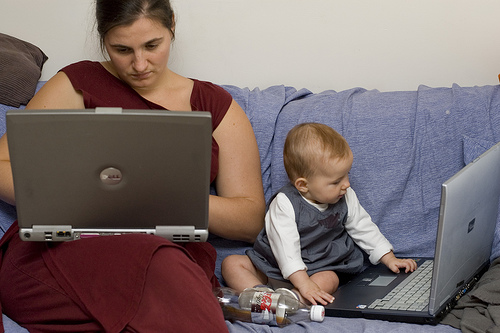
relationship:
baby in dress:
[223, 119, 411, 313] [246, 194, 365, 279]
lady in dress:
[2, 4, 268, 329] [0, 69, 233, 332]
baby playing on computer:
[223, 119, 411, 313] [5, 106, 499, 328]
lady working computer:
[2, 4, 268, 329] [5, 106, 499, 328]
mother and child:
[2, 4, 268, 329] [223, 119, 411, 313]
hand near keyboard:
[382, 244, 418, 276] [327, 257, 436, 316]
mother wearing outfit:
[2, 4, 268, 329] [0, 69, 233, 332]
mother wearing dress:
[2, 4, 268, 329] [246, 194, 365, 279]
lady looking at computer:
[3, 1, 268, 329] [5, 106, 499, 328]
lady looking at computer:
[3, 1, 268, 329] [5, 106, 219, 242]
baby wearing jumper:
[223, 119, 411, 313] [246, 194, 365, 279]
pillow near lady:
[0, 30, 49, 113] [3, 1, 268, 329]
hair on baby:
[280, 123, 350, 174] [223, 119, 411, 313]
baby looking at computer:
[223, 119, 411, 313] [5, 106, 219, 242]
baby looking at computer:
[223, 119, 411, 313] [5, 106, 499, 328]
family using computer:
[7, 6, 411, 332] [5, 106, 219, 242]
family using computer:
[7, 6, 411, 332] [5, 106, 499, 328]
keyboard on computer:
[327, 257, 436, 316] [5, 106, 499, 328]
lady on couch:
[3, 1, 268, 329] [1, 86, 497, 332]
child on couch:
[223, 119, 411, 313] [1, 86, 497, 332]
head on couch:
[280, 121, 359, 208] [1, 86, 497, 332]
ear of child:
[291, 175, 311, 195] [223, 119, 411, 313]